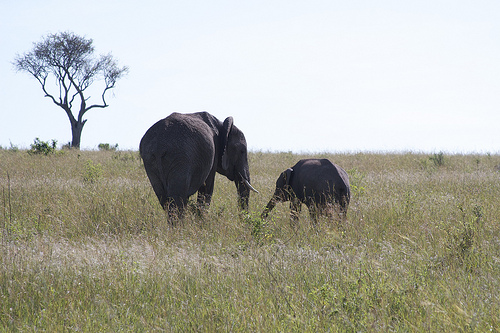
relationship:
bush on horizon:
[412, 145, 451, 172] [348, 131, 491, 162]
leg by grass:
[177, 186, 233, 236] [72, 227, 131, 307]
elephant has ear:
[129, 73, 379, 271] [211, 115, 234, 165]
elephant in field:
[129, 73, 379, 271] [4, 154, 499, 330]